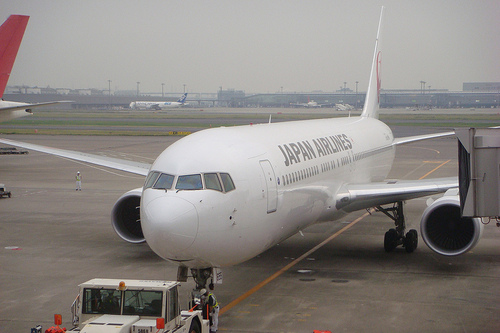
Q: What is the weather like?
A: It is cloudy.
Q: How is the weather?
A: It is cloudy.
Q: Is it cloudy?
A: Yes, it is cloudy.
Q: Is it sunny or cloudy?
A: It is cloudy.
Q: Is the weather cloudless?
A: No, it is cloudy.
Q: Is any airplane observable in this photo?
A: Yes, there is an airplane.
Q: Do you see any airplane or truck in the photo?
A: Yes, there is an airplane.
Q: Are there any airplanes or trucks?
A: Yes, there is an airplane.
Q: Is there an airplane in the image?
A: Yes, there is an airplane.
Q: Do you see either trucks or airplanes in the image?
A: Yes, there is an airplane.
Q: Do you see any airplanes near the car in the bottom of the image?
A: Yes, there is an airplane near the car.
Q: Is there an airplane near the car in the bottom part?
A: Yes, there is an airplane near the car.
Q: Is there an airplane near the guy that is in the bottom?
A: Yes, there is an airplane near the guy.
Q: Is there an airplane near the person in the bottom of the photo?
A: Yes, there is an airplane near the guy.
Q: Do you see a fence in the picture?
A: No, there are no fences.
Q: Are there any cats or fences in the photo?
A: No, there are no fences or cats.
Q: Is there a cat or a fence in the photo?
A: No, there are no fences or cats.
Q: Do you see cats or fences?
A: No, there are no fences or cats.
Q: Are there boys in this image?
A: No, there are no boys.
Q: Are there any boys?
A: No, there are no boys.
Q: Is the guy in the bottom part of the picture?
A: Yes, the guy is in the bottom of the image.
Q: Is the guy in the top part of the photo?
A: No, the guy is in the bottom of the image.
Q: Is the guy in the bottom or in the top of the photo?
A: The guy is in the bottom of the image.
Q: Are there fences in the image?
A: No, there are no fences.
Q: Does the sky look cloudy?
A: Yes, the sky is cloudy.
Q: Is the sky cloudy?
A: Yes, the sky is cloudy.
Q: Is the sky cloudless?
A: No, the sky is cloudy.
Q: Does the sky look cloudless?
A: No, the sky is cloudy.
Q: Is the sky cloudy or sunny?
A: The sky is cloudy.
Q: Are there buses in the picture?
A: No, there are no buses.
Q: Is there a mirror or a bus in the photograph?
A: No, there are no buses or mirrors.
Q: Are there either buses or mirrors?
A: No, there are no buses or mirrors.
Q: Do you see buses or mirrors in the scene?
A: No, there are no buses or mirrors.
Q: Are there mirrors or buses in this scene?
A: No, there are no buses or mirrors.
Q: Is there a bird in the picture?
A: No, there are no birds.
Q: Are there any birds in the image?
A: No, there are no birds.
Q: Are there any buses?
A: No, there are no buses.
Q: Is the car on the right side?
A: No, the car is on the left of the image.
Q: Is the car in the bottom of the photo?
A: Yes, the car is in the bottom of the image.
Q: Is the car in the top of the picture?
A: No, the car is in the bottom of the image.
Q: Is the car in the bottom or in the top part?
A: The car is in the bottom of the image.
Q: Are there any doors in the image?
A: Yes, there is a door.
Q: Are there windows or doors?
A: Yes, there is a door.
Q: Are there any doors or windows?
A: Yes, there is a door.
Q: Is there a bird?
A: No, there are no birds.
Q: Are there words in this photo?
A: Yes, there are words.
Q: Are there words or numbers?
A: Yes, there are words.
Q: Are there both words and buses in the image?
A: No, there are words but no buses.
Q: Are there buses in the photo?
A: No, there are no buses.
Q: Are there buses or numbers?
A: No, there are no buses or numbers.